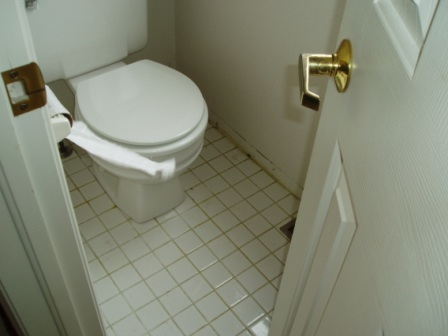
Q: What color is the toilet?
A: White.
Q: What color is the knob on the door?
A: Gold.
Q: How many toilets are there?
A: One.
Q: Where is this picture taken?
A: In a restroom.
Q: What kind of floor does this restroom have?
A: Tile.